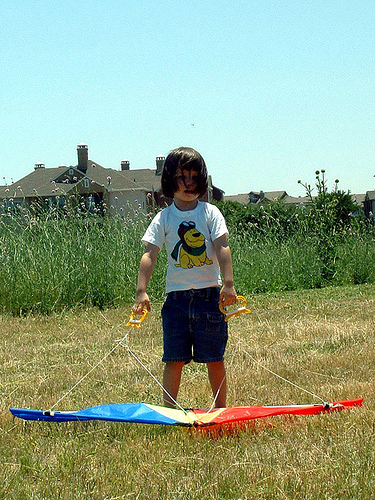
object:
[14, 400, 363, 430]
kite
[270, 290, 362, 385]
ground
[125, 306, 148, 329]
handle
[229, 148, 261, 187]
cloud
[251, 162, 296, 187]
cloud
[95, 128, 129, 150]
cloud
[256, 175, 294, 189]
cloud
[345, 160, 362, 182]
cloud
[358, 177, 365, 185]
cloud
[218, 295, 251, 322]
hook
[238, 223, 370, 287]
grass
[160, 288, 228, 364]
shorts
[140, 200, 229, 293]
shirt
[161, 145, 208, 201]
hair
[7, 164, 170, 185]
roof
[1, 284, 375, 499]
field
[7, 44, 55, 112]
clouds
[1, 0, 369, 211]
sky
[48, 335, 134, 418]
rope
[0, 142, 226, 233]
house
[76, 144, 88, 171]
chimney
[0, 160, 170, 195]
roof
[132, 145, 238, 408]
child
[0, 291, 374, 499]
grass